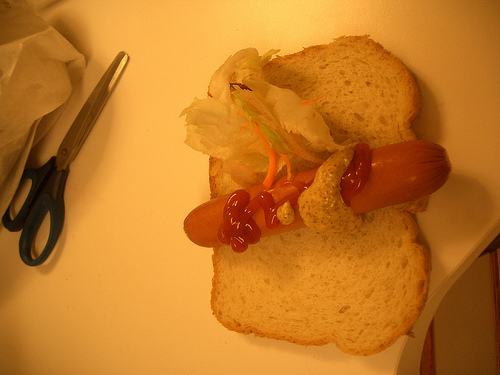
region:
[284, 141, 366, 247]
spicy mustard on top of a hot dog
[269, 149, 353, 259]
spicy mustard mixing with ketcup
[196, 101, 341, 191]
lettuce laying next to a hot dog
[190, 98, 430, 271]
a hotdog laying on a piece of bread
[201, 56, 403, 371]
Food sitting on the counter.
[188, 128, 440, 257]
a hotdog smothered in condiments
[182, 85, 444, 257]
a hotdog garnished with lettuce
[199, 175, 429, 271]
ketchup mixed with spicy mustared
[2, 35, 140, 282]
pair of scissors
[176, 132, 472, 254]
hotdog with mustard and ketchup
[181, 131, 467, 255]
hotdog with ketchup and brown mustard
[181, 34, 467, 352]
hotdog on a piece of bread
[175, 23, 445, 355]
hotdog, bread and lettuce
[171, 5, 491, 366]
hotdog on a table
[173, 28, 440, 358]
prepared hotdog with no plate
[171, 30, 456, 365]
hotdog on slice of bread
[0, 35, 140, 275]
black handled scissors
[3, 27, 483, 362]
scissors and a hotdog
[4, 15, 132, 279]
this is a pair of scissors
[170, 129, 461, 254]
this is a sausage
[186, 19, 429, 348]
this is a slice of bread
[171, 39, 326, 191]
this is a leaf of lettuce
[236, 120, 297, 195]
a stripe of carrot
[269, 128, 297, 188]
a stripe of carrot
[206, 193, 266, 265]
a stripe of carrot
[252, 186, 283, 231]
a stripe of carrot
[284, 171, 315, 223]
a stripe of carrot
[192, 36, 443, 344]
Bread with sausage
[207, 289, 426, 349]
Brown color bread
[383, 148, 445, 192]
Brown color sausage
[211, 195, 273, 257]
Red color tomato sauce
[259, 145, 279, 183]
Orange color carrot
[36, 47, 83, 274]
Black color handle scissors kept in the table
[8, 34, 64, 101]
White color napkin near the scissors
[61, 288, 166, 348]
White color wooden table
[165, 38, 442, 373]
Sandwich kept in the wooden table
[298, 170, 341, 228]
Some cream kept on the sausage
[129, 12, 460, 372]
a hot dog on a bread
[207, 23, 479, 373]
a hotdog with lettuce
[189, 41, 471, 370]
a hotdog with ketchup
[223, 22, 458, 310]
a hotdog with mustard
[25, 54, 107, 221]
scissors on the table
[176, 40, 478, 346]
bread on the table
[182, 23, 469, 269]
a hotdog on a table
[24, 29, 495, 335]
a table with hotdog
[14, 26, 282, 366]
a table with scissors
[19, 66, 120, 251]
a small pair of scissors